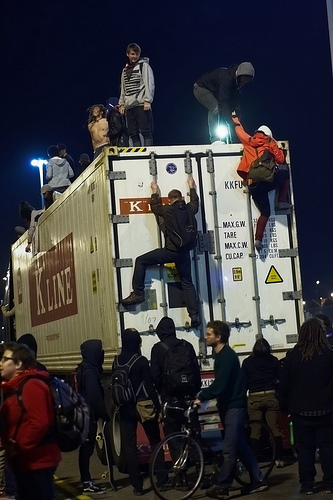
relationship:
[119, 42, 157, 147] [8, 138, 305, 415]
person on top of truck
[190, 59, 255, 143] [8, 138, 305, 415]
person on top of truck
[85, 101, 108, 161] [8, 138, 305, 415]
person on top of truck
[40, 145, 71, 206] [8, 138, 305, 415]
person on top of truck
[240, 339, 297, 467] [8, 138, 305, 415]
person standing behind a truck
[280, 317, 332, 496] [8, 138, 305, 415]
person standing behind a truck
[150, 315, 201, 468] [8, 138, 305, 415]
person standing behind a truck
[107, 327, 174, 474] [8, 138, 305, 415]
person standing behind a truck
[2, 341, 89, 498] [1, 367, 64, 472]
person wearing a jacket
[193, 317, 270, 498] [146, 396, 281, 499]
man holding on to a bicycle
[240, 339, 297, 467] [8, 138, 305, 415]
person behind truck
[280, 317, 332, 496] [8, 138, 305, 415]
person behind truck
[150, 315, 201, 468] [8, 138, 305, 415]
person behind truck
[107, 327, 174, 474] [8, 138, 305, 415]
person behind truck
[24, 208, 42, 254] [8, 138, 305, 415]
leg hanging off truck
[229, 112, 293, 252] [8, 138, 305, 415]
man climbing up truck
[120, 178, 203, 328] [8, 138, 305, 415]
man climbing up truck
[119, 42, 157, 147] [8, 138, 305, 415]
person standing on truck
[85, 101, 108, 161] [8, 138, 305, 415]
person standing on truck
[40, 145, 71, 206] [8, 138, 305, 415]
person standing on truck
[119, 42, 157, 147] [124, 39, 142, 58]
person has short hair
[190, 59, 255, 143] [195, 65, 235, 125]
person wearing a jacket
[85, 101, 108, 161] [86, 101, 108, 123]
person has long hair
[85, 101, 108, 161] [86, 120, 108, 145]
man not wearing a shirt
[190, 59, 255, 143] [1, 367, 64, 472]
person wearing a jacket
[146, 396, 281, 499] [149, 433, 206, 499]
bicycle has a tire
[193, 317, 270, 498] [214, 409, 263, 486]
man wearing jeans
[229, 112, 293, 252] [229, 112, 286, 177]
man wearing a jacket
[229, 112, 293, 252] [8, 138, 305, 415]
man climbing on truck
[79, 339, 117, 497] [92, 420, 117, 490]
man holding skateboard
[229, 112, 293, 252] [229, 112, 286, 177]
man wearing jacket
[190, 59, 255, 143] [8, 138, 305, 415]
person standing on truck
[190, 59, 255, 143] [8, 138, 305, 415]
person on truck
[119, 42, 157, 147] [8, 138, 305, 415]
person on truck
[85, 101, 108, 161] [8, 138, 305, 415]
person on truck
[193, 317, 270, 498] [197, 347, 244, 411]
man wearing a shirt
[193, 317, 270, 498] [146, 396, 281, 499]
man holding bicycle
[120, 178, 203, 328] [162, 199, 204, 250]
man wearing a backpack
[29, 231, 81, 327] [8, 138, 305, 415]
logo on truck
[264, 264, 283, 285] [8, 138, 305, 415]
hazard label on truck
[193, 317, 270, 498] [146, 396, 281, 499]
man holding on to bicycle